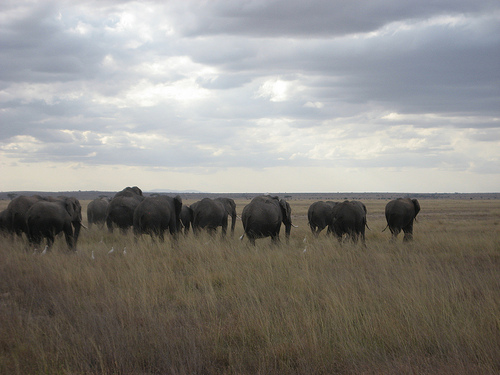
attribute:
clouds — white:
[83, 47, 220, 136]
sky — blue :
[46, 8, 493, 144]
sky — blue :
[93, 17, 444, 177]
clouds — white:
[316, 84, 389, 128]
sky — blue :
[57, 8, 485, 178]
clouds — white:
[370, 81, 460, 141]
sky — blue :
[74, 25, 483, 164]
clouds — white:
[95, 70, 149, 114]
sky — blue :
[155, 51, 479, 190]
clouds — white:
[139, 49, 203, 92]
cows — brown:
[16, 190, 425, 245]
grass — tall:
[14, 243, 495, 365]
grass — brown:
[3, 242, 458, 371]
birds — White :
[47, 238, 181, 272]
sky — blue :
[11, 32, 111, 89]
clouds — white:
[22, 28, 97, 125]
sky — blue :
[38, 32, 468, 177]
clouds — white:
[330, 52, 416, 114]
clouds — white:
[386, 13, 476, 78]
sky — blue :
[2, 2, 497, 191]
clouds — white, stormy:
[3, 0, 496, 172]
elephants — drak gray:
[0, 186, 420, 247]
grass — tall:
[0, 192, 497, 369]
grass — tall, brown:
[0, 227, 497, 371]